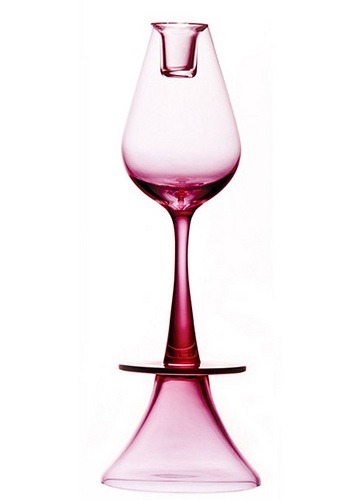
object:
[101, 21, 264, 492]
glass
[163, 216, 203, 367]
middle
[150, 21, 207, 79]
cube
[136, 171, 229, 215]
wine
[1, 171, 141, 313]
background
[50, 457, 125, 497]
floor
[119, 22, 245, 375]
cup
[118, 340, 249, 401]
stand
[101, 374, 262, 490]
base